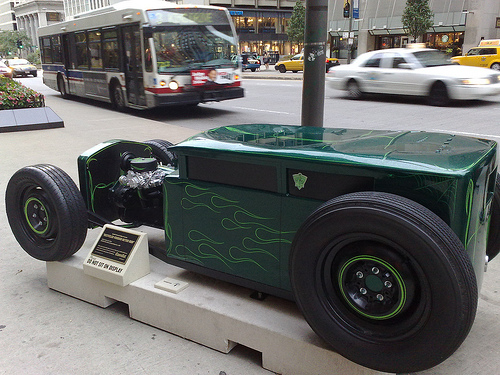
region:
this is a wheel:
[7, 159, 80, 259]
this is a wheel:
[286, 203, 468, 359]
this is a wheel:
[155, 137, 169, 162]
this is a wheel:
[109, 78, 125, 106]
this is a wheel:
[53, 74, 68, 96]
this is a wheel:
[344, 74, 359, 104]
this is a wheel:
[427, 83, 449, 103]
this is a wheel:
[279, 68, 286, 77]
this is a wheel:
[247, 65, 258, 74]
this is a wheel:
[492, 57, 498, 74]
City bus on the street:
[34, 0, 246, 115]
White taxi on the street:
[327, 38, 497, 104]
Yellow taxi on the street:
[448, 42, 497, 71]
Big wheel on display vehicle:
[287, 191, 480, 372]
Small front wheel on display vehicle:
[2, 160, 84, 267]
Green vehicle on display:
[4, 122, 499, 374]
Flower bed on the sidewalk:
[0, 78, 45, 110]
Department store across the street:
[330, 1, 497, 66]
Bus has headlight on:
[167, 79, 179, 91]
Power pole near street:
[300, 1, 327, 130]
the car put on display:
[5, 120, 497, 374]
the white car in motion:
[324, 46, 499, 103]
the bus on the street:
[36, 0, 244, 112]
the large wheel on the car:
[287, 190, 480, 373]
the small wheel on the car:
[2, 162, 85, 259]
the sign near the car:
[81, 223, 151, 285]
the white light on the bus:
[168, 80, 178, 90]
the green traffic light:
[14, 35, 24, 50]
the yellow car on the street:
[274, 51, 339, 73]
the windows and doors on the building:
[232, 15, 302, 57]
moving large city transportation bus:
[39, 3, 251, 112]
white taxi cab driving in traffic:
[328, 45, 499, 110]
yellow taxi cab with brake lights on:
[273, 50, 339, 75]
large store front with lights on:
[236, 1, 301, 77]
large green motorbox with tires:
[11, 105, 498, 374]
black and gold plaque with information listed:
[88, 221, 144, 287]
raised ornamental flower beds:
[0, 73, 50, 103]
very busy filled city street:
[259, 80, 301, 119]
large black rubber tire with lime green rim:
[286, 190, 478, 371]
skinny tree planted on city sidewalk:
[397, 0, 438, 49]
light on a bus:
[165, 73, 186, 100]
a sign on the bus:
[194, 56, 252, 87]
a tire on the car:
[426, 76, 453, 108]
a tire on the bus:
[103, 80, 139, 114]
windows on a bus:
[70, 37, 131, 78]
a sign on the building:
[335, 3, 379, 24]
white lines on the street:
[257, 97, 280, 122]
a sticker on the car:
[289, 164, 311, 190]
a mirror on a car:
[394, 55, 416, 75]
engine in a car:
[120, 151, 153, 213]